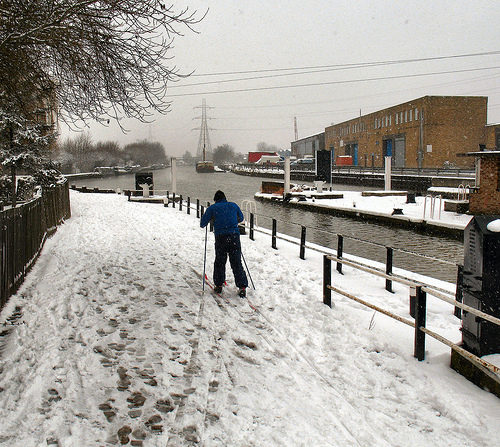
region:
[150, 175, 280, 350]
cross country skier on sidewalk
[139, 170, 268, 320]
skier in blue jacket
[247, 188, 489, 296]
canal beside the sidewalk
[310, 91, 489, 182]
building by the water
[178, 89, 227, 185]
tower for power wires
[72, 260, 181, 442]
tracks in the snow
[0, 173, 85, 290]
wall beside the walkway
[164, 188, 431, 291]
railing along the water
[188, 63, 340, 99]
wires hanging overhead the scene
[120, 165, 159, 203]
a sign in the water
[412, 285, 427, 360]
black wooden fence post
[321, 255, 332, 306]
black wooden fence post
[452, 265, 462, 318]
black wooden fence post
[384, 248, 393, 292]
black wooden fence post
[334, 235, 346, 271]
black wooden fence post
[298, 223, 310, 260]
black wooden fence post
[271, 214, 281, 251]
black wooden fence post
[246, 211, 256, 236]
black wooden fence post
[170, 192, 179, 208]
black wooden fence post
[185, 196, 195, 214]
black wooden fence post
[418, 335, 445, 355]
edge of a pole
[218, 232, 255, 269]
back of a man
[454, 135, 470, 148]
part of a building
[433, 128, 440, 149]
edge of a building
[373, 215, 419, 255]
part of the river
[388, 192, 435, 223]
part of a dork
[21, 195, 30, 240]
part of a fence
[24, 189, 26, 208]
edge of a fence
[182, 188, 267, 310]
a man skiing down the sidewalk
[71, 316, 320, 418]
white snow on the ground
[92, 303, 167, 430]
several sets of footprints in the snow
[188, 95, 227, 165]
an elctrical tower in the distance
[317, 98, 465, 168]
a brown building with blue doors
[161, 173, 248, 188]
calm black water of the river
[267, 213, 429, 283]
black metal fence on the sidewalk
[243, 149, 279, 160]
red truck parked next to the building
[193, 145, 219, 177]
a barge traveling down the river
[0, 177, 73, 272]
wooden fence next to the sidewalk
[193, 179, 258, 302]
person walking in the snow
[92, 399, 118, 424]
footprint in the snow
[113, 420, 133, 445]
footprint in the snow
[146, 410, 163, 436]
footprint in the snow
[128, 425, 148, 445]
footprint in the snow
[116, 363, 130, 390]
footprint in the snow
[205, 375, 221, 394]
footprint in the snow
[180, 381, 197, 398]
footprint in the snow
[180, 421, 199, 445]
footprint in the snow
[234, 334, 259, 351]
footprint in the snow